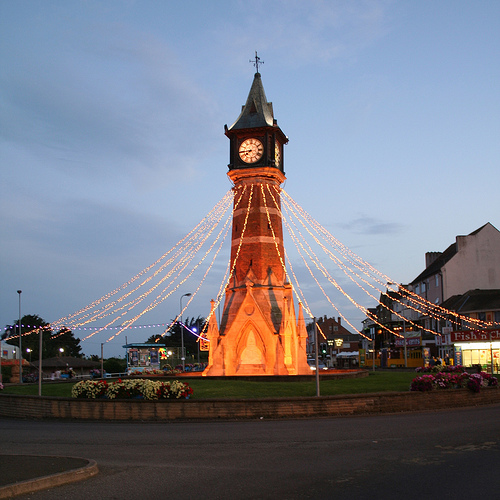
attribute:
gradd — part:
[251, 408, 271, 428]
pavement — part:
[147, 426, 236, 459]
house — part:
[365, 224, 498, 371]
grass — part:
[1, 369, 441, 399]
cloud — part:
[174, 290, 199, 318]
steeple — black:
[240, 46, 265, 79]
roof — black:
[417, 245, 458, 273]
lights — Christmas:
[14, 184, 479, 373]